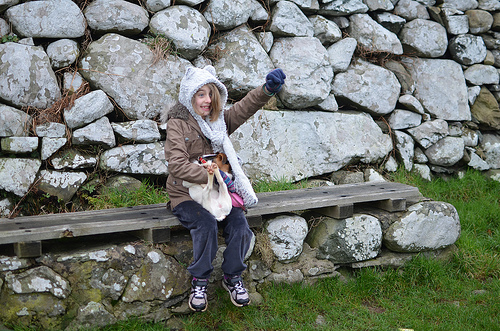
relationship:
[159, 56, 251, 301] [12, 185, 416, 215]
girl on bench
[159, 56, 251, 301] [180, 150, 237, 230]
girl with animal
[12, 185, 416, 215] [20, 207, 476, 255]
bench on top of rocks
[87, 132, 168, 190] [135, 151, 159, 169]
rocks have dark grey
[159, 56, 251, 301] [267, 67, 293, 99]
girl wearing glove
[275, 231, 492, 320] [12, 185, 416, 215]
grass by bench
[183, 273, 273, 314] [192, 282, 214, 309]
shoes has laces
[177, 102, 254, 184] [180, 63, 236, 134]
scarf on hat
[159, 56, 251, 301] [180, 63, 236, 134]
girl wearing hat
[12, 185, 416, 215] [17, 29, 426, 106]
bench by wall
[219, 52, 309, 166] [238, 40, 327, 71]
arm in air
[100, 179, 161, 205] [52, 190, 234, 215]
blades of grass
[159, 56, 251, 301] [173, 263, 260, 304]
girl wearing sneakers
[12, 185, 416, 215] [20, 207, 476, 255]
bench on rocks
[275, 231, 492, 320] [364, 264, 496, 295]
grass covering ground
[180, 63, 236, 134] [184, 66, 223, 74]
hat has ears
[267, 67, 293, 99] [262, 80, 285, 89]
glove on hand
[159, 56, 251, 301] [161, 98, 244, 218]
girl wears coat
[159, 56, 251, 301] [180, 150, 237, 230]
girl holding items